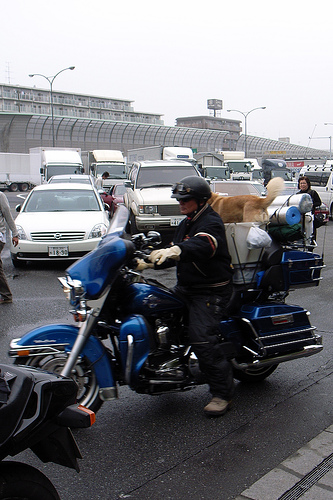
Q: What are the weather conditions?
A: It is overcast.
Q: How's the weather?
A: It is overcast.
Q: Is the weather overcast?
A: Yes, it is overcast.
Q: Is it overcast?
A: Yes, it is overcast.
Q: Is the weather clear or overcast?
A: It is overcast.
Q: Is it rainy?
A: No, it is overcast.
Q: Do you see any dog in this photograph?
A: Yes, there is a dog.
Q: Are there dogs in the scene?
A: Yes, there is a dog.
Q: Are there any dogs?
A: Yes, there is a dog.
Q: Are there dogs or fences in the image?
A: Yes, there is a dog.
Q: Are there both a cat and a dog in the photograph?
A: No, there is a dog but no cats.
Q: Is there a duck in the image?
A: No, there are no ducks.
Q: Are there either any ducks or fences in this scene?
A: No, there are no ducks or fences.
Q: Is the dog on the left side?
A: No, the dog is on the right of the image.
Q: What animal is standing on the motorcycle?
A: The dog is standing on the motorbike.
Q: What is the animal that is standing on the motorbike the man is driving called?
A: The animal is a dog.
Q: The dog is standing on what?
A: The dog is standing on the motorcycle.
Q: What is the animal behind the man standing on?
A: The dog is standing on the motorcycle.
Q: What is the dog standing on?
A: The dog is standing on the motorcycle.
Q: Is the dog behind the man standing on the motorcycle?
A: Yes, the dog is standing on the motorcycle.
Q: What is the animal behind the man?
A: The animal is a dog.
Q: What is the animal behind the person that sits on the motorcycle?
A: The animal is a dog.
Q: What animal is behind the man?
A: The animal is a dog.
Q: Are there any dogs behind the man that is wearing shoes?
A: Yes, there is a dog behind the man.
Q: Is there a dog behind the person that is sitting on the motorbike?
A: Yes, there is a dog behind the man.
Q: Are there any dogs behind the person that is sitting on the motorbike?
A: Yes, there is a dog behind the man.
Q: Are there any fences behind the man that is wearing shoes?
A: No, there is a dog behind the man.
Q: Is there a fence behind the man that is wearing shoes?
A: No, there is a dog behind the man.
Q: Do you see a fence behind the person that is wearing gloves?
A: No, there is a dog behind the man.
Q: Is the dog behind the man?
A: Yes, the dog is behind the man.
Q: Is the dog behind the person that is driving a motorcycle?
A: Yes, the dog is behind the man.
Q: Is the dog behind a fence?
A: No, the dog is behind the man.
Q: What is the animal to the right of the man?
A: The animal is a dog.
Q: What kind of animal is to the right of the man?
A: The animal is a dog.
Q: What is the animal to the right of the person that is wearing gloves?
A: The animal is a dog.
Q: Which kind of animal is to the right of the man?
A: The animal is a dog.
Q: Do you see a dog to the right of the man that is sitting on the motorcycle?
A: Yes, there is a dog to the right of the man.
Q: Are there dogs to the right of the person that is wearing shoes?
A: Yes, there is a dog to the right of the man.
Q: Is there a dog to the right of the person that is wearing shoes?
A: Yes, there is a dog to the right of the man.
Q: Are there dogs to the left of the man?
A: No, the dog is to the right of the man.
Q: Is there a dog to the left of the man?
A: No, the dog is to the right of the man.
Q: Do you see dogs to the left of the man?
A: No, the dog is to the right of the man.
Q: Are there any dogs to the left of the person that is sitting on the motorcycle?
A: No, the dog is to the right of the man.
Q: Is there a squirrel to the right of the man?
A: No, there is a dog to the right of the man.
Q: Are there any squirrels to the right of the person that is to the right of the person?
A: No, there is a dog to the right of the man.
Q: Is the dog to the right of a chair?
A: No, the dog is to the right of the man.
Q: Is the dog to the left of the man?
A: No, the dog is to the right of the man.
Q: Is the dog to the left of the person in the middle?
A: No, the dog is to the right of the man.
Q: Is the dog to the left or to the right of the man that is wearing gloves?
A: The dog is to the right of the man.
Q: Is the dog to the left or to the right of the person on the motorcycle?
A: The dog is to the right of the man.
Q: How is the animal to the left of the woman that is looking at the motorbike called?
A: The animal is a dog.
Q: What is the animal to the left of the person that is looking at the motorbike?
A: The animal is a dog.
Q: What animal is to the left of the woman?
A: The animal is a dog.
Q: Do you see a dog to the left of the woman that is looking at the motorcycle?
A: Yes, there is a dog to the left of the woman.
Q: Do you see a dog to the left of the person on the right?
A: Yes, there is a dog to the left of the woman.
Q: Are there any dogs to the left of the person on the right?
A: Yes, there is a dog to the left of the woman.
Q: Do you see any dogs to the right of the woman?
A: No, the dog is to the left of the woman.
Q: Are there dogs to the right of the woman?
A: No, the dog is to the left of the woman.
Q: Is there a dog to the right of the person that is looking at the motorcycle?
A: No, the dog is to the left of the woman.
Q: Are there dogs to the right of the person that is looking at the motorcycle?
A: No, the dog is to the left of the woman.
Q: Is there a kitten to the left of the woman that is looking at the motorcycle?
A: No, there is a dog to the left of the woman.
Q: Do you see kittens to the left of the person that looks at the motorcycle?
A: No, there is a dog to the left of the woman.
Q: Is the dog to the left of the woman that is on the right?
A: Yes, the dog is to the left of the woman.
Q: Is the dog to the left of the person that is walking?
A: Yes, the dog is to the left of the woman.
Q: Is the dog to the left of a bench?
A: No, the dog is to the left of the woman.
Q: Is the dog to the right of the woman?
A: No, the dog is to the left of the woman.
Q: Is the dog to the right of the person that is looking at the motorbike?
A: No, the dog is to the left of the woman.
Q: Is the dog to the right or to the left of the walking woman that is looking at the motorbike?
A: The dog is to the left of the woman.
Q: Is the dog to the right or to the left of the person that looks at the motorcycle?
A: The dog is to the left of the woman.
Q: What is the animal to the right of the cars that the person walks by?
A: The animal is a dog.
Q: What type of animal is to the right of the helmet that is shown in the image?
A: The animal is a dog.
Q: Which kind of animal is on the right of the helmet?
A: The animal is a dog.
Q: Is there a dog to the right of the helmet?
A: Yes, there is a dog to the right of the helmet.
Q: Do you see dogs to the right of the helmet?
A: Yes, there is a dog to the right of the helmet.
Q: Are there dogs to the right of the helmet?
A: Yes, there is a dog to the right of the helmet.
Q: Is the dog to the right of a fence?
A: No, the dog is to the right of a helmet.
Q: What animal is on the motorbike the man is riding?
A: The animal is a dog.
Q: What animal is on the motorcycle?
A: The animal is a dog.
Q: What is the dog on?
A: The dog is on the motorcycle.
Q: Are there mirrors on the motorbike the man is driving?
A: No, there is a dog on the motorcycle.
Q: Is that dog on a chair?
A: No, the dog is on a motorcycle.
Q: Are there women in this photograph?
A: Yes, there is a woman.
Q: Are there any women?
A: Yes, there is a woman.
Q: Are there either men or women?
A: Yes, there is a woman.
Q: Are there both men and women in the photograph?
A: Yes, there are both a woman and a man.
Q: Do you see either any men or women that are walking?
A: Yes, the woman is walking.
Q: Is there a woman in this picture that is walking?
A: Yes, there is a woman that is walking.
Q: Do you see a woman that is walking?
A: Yes, there is a woman that is walking.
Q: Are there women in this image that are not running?
A: Yes, there is a woman that is walking.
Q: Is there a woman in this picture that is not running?
A: Yes, there is a woman that is walking.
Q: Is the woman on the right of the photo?
A: Yes, the woman is on the right of the image.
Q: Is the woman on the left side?
A: No, the woman is on the right of the image.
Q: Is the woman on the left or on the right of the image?
A: The woman is on the right of the image.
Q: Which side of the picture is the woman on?
A: The woman is on the right of the image.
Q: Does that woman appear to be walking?
A: Yes, the woman is walking.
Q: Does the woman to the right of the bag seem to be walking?
A: Yes, the woman is walking.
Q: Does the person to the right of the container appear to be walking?
A: Yes, the woman is walking.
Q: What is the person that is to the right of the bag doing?
A: The woman is walking.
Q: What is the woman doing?
A: The woman is walking.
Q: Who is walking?
A: The woman is walking.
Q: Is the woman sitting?
A: No, the woman is walking.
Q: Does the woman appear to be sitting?
A: No, the woman is walking.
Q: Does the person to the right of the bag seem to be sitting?
A: No, the woman is walking.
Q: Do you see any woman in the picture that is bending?
A: No, there is a woman but she is walking.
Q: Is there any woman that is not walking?
A: No, there is a woman but she is walking.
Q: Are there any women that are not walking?
A: No, there is a woman but she is walking.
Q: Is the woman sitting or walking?
A: The woman is walking.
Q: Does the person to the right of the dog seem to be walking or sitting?
A: The woman is walking.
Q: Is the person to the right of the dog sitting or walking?
A: The woman is walking.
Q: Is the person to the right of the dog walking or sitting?
A: The woman is walking.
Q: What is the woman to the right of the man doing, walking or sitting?
A: The woman is walking.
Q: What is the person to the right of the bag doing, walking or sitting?
A: The woman is walking.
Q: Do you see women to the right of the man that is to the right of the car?
A: Yes, there is a woman to the right of the man.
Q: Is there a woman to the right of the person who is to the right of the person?
A: Yes, there is a woman to the right of the man.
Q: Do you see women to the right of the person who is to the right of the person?
A: Yes, there is a woman to the right of the man.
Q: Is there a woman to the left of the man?
A: No, the woman is to the right of the man.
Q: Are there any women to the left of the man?
A: No, the woman is to the right of the man.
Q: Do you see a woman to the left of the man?
A: No, the woman is to the right of the man.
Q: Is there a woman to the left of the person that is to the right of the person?
A: No, the woman is to the right of the man.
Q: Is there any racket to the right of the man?
A: No, there is a woman to the right of the man.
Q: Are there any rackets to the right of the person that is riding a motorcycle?
A: No, there is a woman to the right of the man.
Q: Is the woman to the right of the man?
A: Yes, the woman is to the right of the man.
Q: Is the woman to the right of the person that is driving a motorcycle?
A: Yes, the woman is to the right of the man.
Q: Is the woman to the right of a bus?
A: No, the woman is to the right of the man.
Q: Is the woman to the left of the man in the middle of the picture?
A: No, the woman is to the right of the man.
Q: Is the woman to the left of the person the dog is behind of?
A: No, the woman is to the right of the man.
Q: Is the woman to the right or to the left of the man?
A: The woman is to the right of the man.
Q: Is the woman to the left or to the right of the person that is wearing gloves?
A: The woman is to the right of the man.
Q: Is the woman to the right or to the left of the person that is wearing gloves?
A: The woman is to the right of the man.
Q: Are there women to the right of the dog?
A: Yes, there is a woman to the right of the dog.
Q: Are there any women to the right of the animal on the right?
A: Yes, there is a woman to the right of the dog.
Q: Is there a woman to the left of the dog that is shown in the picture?
A: No, the woman is to the right of the dog.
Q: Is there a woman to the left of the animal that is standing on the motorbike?
A: No, the woman is to the right of the dog.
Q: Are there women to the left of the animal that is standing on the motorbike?
A: No, the woman is to the right of the dog.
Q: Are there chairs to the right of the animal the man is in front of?
A: No, there is a woman to the right of the dog.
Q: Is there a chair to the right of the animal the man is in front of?
A: No, there is a woman to the right of the dog.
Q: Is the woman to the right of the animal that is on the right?
A: Yes, the woman is to the right of the dog.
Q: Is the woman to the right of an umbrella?
A: No, the woman is to the right of the dog.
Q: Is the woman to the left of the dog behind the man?
A: No, the woman is to the right of the dog.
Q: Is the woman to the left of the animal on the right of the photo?
A: No, the woman is to the right of the dog.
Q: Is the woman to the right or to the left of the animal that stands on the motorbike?
A: The woman is to the right of the dog.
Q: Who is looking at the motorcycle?
A: The woman is looking at the motorcycle.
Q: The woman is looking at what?
A: The woman is looking at the motorcycle.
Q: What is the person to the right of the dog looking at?
A: The woman is looking at the motorcycle.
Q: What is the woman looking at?
A: The woman is looking at the motorcycle.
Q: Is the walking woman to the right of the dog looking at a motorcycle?
A: Yes, the woman is looking at a motorcycle.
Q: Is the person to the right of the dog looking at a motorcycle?
A: Yes, the woman is looking at a motorcycle.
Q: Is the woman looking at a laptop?
A: No, the woman is looking at a motorcycle.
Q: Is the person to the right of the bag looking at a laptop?
A: No, the woman is looking at a motorcycle.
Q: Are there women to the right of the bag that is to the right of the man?
A: Yes, there is a woman to the right of the bag.